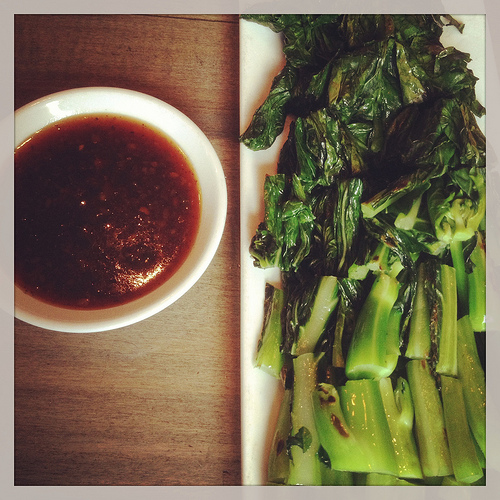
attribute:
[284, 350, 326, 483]
vegetable — cut up, green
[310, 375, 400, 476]
vegetable — cut up, green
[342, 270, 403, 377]
vegetable — cut up, green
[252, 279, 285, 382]
vegetable — cut up, green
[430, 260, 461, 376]
vegetable — cut up, green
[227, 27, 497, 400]
tray — rectangle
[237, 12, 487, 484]
food — green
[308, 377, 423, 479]
vege — fried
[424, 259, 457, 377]
vege — fried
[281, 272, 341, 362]
vege — fried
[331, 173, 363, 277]
vege — fried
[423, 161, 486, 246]
vege — fried